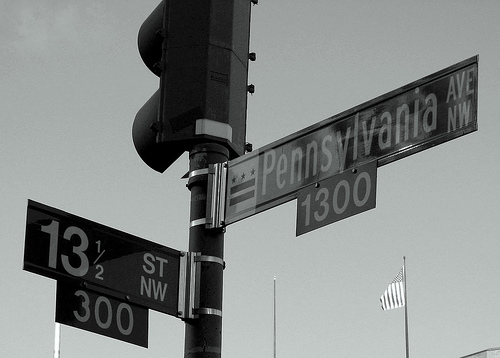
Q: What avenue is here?
A: Pennsylvania Avenue.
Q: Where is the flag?
A: On the pole.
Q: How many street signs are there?
A: Two.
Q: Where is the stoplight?
A: Over the street signs.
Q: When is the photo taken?
A: Daytime.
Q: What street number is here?
A: 13 and a half.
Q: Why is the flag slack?
A: It is not windy.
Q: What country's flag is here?
A: USA.